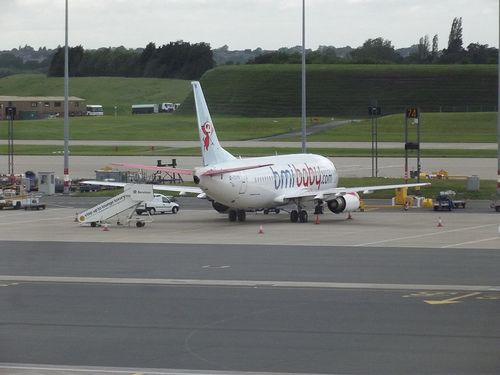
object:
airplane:
[78, 80, 432, 222]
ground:
[0, 113, 500, 375]